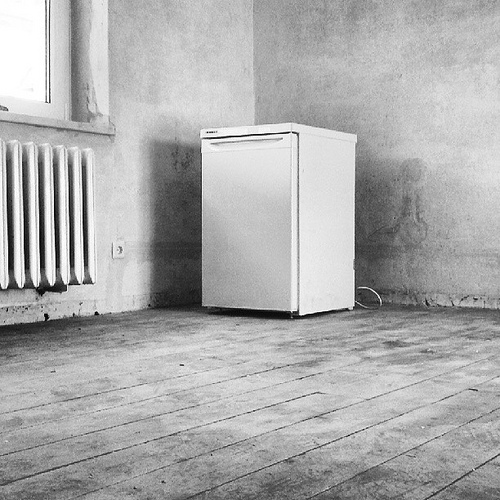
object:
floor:
[0, 312, 499, 494]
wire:
[355, 286, 382, 310]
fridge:
[200, 122, 358, 319]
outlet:
[113, 241, 126, 258]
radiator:
[0, 140, 97, 289]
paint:
[355, 286, 500, 308]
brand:
[204, 130, 218, 135]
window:
[0, 0, 71, 121]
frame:
[0, 0, 75, 122]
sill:
[2, 109, 115, 137]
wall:
[358, 160, 499, 262]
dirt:
[1, 322, 99, 351]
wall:
[255, 0, 498, 310]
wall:
[0, 0, 254, 327]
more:
[3, 298, 498, 500]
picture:
[0, 0, 500, 499]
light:
[0, 0, 52, 100]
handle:
[206, 135, 297, 146]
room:
[0, 0, 500, 499]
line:
[0, 354, 500, 400]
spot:
[394, 156, 426, 187]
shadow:
[198, 302, 356, 320]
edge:
[248, 0, 259, 120]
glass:
[0, 0, 47, 102]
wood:
[0, 362, 499, 497]